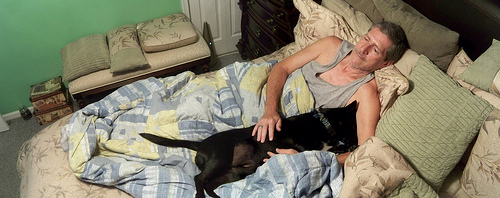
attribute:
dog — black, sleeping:
[138, 98, 357, 198]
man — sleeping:
[251, 22, 408, 165]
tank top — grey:
[301, 40, 353, 111]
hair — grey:
[368, 21, 409, 64]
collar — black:
[315, 109, 335, 135]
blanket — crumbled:
[63, 60, 343, 197]